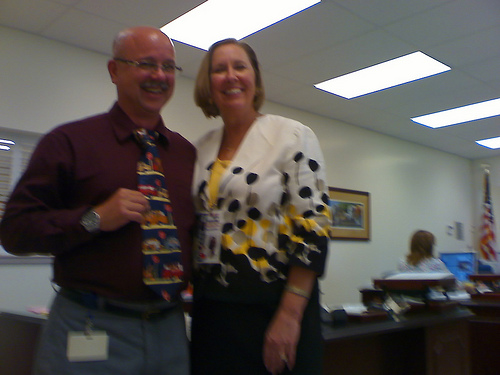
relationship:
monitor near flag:
[438, 252, 477, 286] [477, 172, 497, 264]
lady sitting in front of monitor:
[397, 229, 464, 294] [438, 252, 477, 286]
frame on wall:
[327, 185, 373, 242] [1, 25, 474, 307]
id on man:
[67, 317, 109, 360] [1, 26, 199, 373]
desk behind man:
[0, 307, 476, 373] [1, 26, 199, 373]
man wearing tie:
[1, 26, 199, 373] [133, 127, 186, 303]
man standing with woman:
[1, 26, 199, 373] [189, 38, 332, 373]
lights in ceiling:
[160, 0, 499, 151] [0, 0, 499, 162]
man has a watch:
[1, 26, 199, 373] [81, 205, 104, 238]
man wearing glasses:
[1, 26, 199, 373] [110, 55, 183, 78]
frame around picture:
[327, 185, 373, 242] [326, 198, 365, 231]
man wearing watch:
[1, 26, 199, 373] [81, 205, 104, 238]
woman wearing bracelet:
[189, 38, 332, 373] [282, 282, 312, 301]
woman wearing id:
[189, 38, 332, 373] [193, 209, 225, 264]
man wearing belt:
[1, 26, 199, 373] [56, 282, 183, 321]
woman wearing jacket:
[189, 38, 332, 373] [191, 113, 331, 305]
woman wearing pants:
[189, 38, 332, 373] [190, 277, 324, 372]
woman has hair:
[189, 38, 332, 373] [194, 37, 265, 120]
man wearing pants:
[1, 26, 199, 373] [35, 283, 191, 373]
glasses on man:
[110, 55, 183, 78] [1, 26, 199, 373]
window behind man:
[1, 127, 56, 267] [1, 26, 199, 373]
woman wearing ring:
[189, 38, 332, 373] [276, 351, 290, 365]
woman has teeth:
[189, 38, 332, 373] [223, 88, 244, 96]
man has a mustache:
[1, 26, 199, 373] [140, 77, 169, 92]